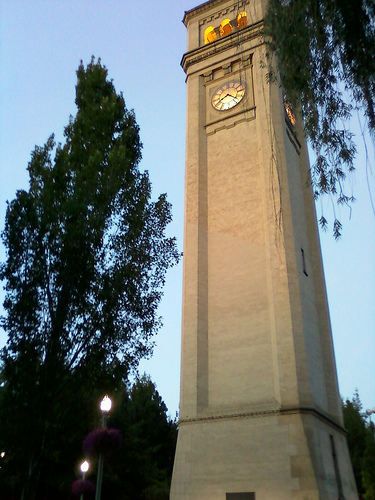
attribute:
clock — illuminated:
[210, 79, 246, 112]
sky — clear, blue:
[1, 1, 363, 423]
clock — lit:
[193, 74, 252, 119]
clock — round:
[210, 81, 254, 115]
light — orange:
[195, 10, 245, 46]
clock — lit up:
[206, 77, 254, 114]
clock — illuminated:
[197, 71, 259, 114]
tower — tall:
[177, 4, 324, 408]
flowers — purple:
[86, 425, 123, 456]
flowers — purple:
[83, 428, 123, 452]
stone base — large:
[168, 416, 322, 498]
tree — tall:
[7, 52, 169, 398]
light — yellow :
[206, 23, 214, 37]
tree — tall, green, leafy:
[18, 49, 175, 404]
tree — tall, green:
[11, 59, 173, 414]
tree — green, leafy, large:
[275, 17, 362, 131]